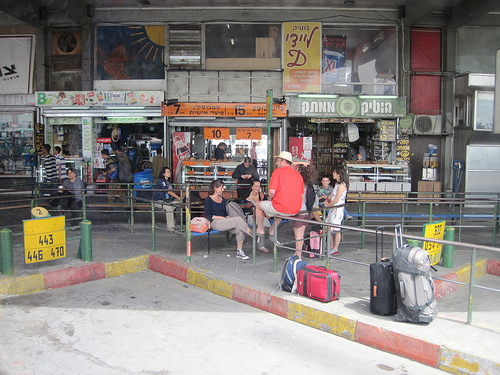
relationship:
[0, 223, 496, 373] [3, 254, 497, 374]
sidewalk has curb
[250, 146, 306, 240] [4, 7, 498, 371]
man at bus terminal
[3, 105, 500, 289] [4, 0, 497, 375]
stores at bus terminal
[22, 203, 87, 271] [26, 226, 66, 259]
sign with numbers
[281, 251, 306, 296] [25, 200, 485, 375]
back pack on sidewalk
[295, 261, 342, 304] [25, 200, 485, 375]
luggage on sidewalk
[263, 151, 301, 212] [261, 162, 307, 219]
guy in shirt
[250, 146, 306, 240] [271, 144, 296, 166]
man with white hat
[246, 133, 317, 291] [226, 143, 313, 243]
man with shirt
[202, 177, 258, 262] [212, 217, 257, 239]
person with leg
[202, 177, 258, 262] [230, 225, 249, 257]
person with leg